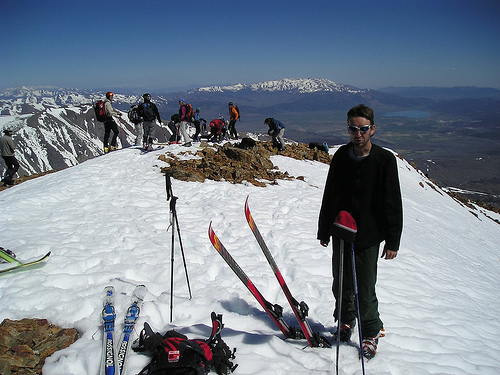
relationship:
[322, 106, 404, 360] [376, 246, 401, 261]
man has hand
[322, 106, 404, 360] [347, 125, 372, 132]
man has glasses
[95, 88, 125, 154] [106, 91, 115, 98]
man has helmet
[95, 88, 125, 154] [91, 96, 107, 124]
man has backpack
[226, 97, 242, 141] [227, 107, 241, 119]
man has jacket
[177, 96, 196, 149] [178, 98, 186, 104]
man has hat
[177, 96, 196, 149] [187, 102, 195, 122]
man has backpack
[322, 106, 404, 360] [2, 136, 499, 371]
skier on moutain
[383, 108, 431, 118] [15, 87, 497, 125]
lake in background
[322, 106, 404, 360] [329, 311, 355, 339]
man in ski boot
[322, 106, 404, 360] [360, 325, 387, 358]
man in ski boot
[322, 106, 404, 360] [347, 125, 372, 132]
man wearing glasses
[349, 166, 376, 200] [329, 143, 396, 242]
part of coat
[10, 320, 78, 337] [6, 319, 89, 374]
edge of rock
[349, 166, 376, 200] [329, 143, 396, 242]
part of sweater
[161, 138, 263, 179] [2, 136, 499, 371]
part of mountain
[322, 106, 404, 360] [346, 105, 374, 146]
man has face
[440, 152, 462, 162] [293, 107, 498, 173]
part of plain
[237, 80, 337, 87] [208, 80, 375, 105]
snow on mountain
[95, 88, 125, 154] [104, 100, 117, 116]
person wearing jacket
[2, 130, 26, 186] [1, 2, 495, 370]
person in shot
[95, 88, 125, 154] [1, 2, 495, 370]
person in shot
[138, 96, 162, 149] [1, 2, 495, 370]
person in shot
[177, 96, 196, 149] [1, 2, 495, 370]
person in shot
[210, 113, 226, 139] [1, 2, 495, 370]
person in shot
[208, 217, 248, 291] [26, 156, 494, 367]
ski in snow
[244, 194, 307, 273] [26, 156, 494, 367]
ski in snow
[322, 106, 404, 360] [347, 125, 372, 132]
person wearing goggles